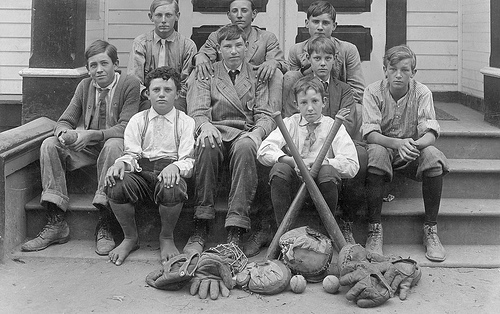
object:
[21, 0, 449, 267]
group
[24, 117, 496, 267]
steps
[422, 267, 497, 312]
floor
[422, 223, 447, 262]
shoe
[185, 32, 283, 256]
boy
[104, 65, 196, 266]
boy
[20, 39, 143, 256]
boy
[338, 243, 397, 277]
glove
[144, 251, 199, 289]
glove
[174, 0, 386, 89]
door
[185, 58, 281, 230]
suit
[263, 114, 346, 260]
baseball bat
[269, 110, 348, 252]
baseball bat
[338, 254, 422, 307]
glove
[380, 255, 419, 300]
glove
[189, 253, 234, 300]
glove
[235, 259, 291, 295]
glove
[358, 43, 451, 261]
boy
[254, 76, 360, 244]
boy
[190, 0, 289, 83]
boy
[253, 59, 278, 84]
hand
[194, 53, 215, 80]
hand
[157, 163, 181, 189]
hand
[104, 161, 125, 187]
hand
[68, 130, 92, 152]
hand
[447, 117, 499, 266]
stairs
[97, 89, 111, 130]
tie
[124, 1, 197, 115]
boys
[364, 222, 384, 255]
shoe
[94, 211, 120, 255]
shoe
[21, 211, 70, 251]
shoe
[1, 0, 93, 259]
column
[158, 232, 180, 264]
foot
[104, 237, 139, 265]
foot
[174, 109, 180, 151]
suspender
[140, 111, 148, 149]
suspender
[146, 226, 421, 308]
gear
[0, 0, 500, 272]
building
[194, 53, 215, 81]
hands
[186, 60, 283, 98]
shoulders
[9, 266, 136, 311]
ground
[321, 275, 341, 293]
ball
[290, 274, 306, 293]
ball